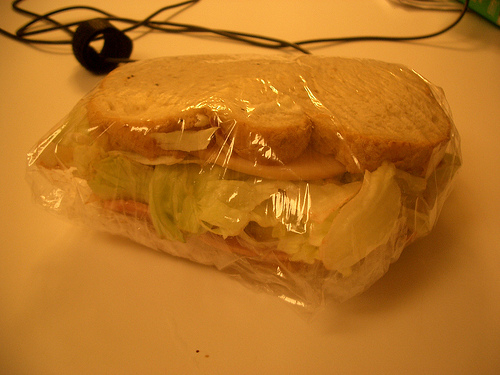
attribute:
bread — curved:
[61, 50, 443, 310]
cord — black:
[0, 2, 500, 75]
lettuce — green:
[182, 160, 323, 250]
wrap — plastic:
[21, 50, 466, 317]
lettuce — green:
[76, 131, 408, 288]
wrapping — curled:
[24, 54, 463, 323]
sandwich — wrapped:
[44, 39, 487, 311]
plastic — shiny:
[23, 43, 466, 317]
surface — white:
[2, 1, 498, 372]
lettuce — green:
[40, 100, 460, 275]